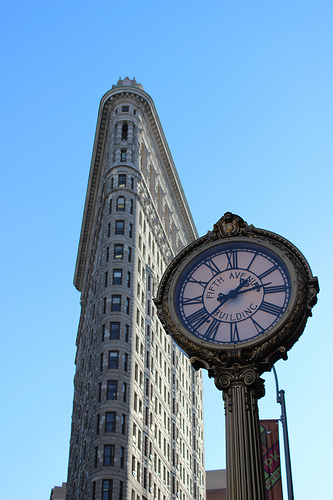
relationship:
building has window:
[48, 71, 214, 499] [114, 193, 127, 213]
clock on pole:
[162, 207, 296, 369] [213, 374, 264, 498]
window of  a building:
[103, 443, 115, 468] [65, 75, 205, 498]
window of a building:
[107, 316, 122, 345] [48, 71, 214, 499]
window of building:
[96, 443, 129, 473] [41, 96, 198, 494]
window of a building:
[102, 409, 116, 433] [65, 75, 205, 498]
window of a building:
[103, 377, 119, 402] [65, 75, 205, 498]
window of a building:
[110, 266, 124, 286] [39, 71, 230, 498]